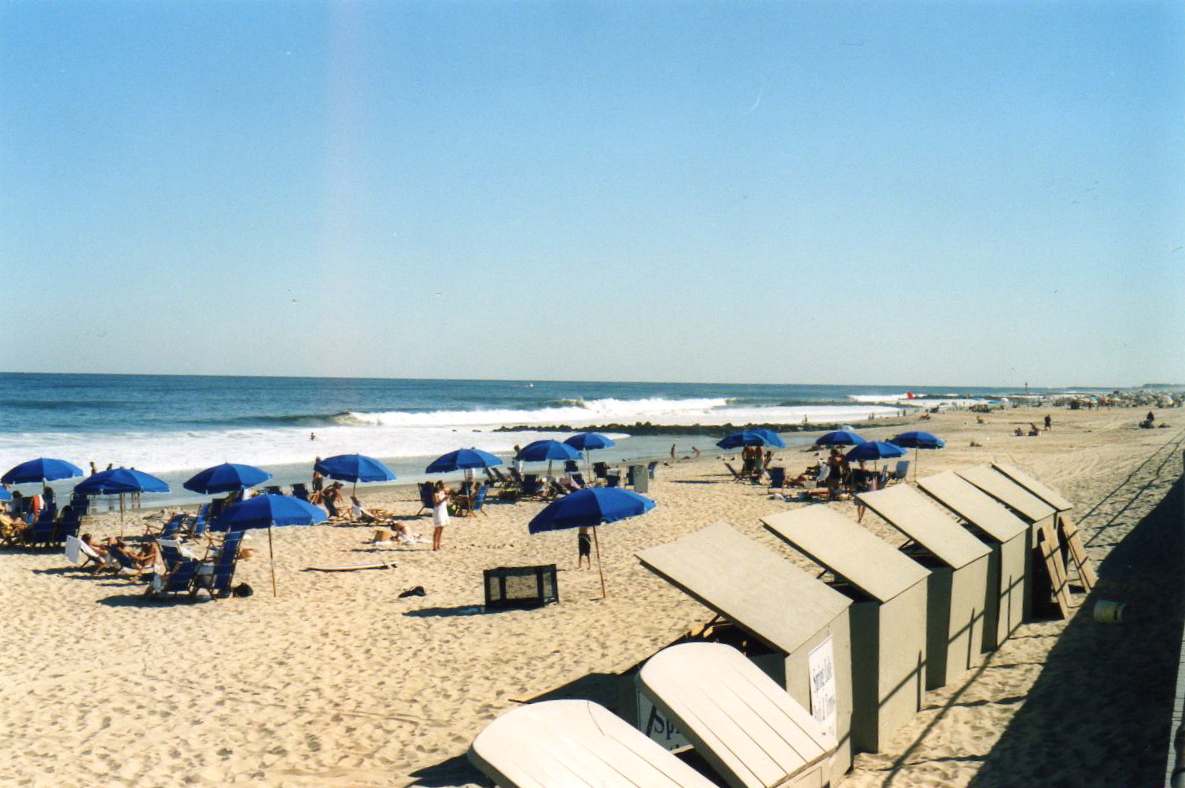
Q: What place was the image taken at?
A: It was taken at the beach.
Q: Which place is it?
A: It is a beach.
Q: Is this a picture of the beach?
A: Yes, it is showing the beach.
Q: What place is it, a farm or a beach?
A: It is a beach.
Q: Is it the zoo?
A: No, it is the beach.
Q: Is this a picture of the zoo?
A: No, the picture is showing the beach.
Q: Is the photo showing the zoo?
A: No, the picture is showing the beach.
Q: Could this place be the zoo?
A: No, it is the beach.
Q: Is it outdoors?
A: Yes, it is outdoors.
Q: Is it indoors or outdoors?
A: It is outdoors.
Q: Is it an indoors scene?
A: No, it is outdoors.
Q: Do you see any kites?
A: No, there are no kites.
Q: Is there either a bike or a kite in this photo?
A: No, there are no kites or bikes.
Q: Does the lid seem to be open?
A: Yes, the lid is open.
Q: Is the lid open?
A: Yes, the lid is open.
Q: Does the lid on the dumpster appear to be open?
A: Yes, the lid is open.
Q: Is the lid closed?
A: No, the lid is open.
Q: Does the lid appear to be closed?
A: No, the lid is open.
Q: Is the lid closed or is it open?
A: The lid is open.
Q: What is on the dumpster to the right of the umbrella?
A: The lid is on the dumpster.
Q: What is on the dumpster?
A: The lid is on the dumpster.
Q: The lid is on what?
A: The lid is on the dumpster.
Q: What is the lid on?
A: The lid is on the dumpster.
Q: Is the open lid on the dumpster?
A: Yes, the lid is on the dumpster.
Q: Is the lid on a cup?
A: No, the lid is on the dumpster.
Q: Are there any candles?
A: No, there are no candles.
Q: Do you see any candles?
A: No, there are no candles.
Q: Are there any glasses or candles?
A: No, there are no candles or glasses.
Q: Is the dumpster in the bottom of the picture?
A: Yes, the dumpster is in the bottom of the image.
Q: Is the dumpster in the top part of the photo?
A: No, the dumpster is in the bottom of the image.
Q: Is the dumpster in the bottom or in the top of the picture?
A: The dumpster is in the bottom of the image.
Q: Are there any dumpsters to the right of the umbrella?
A: Yes, there is a dumpster to the right of the umbrella.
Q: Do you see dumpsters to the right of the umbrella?
A: Yes, there is a dumpster to the right of the umbrella.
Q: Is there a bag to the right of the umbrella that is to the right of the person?
A: No, there is a dumpster to the right of the umbrella.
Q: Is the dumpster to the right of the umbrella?
A: Yes, the dumpster is to the right of the umbrella.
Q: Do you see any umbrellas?
A: Yes, there is an umbrella.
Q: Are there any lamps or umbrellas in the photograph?
A: Yes, there is an umbrella.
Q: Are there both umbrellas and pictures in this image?
A: No, there is an umbrella but no pictures.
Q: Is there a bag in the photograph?
A: No, there are no bags.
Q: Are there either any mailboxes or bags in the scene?
A: No, there are no bags or mailboxes.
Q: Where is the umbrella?
A: The umbrella is on the beach.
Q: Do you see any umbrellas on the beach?
A: Yes, there is an umbrella on the beach.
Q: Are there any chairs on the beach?
A: No, there is an umbrella on the beach.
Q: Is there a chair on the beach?
A: No, there is an umbrella on the beach.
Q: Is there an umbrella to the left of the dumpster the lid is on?
A: Yes, there is an umbrella to the left of the dumpster.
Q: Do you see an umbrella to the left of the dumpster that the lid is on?
A: Yes, there is an umbrella to the left of the dumpster.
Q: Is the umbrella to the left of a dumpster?
A: Yes, the umbrella is to the left of a dumpster.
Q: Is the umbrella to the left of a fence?
A: No, the umbrella is to the left of a dumpster.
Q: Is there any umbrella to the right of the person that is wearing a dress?
A: Yes, there is an umbrella to the right of the person.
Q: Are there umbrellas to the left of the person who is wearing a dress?
A: No, the umbrella is to the right of the person.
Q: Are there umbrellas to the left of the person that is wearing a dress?
A: No, the umbrella is to the right of the person.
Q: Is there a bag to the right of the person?
A: No, there is an umbrella to the right of the person.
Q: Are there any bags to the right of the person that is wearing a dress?
A: No, there is an umbrella to the right of the person.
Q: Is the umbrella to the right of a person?
A: Yes, the umbrella is to the right of a person.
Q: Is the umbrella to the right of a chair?
A: No, the umbrella is to the right of a person.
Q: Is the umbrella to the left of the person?
A: No, the umbrella is to the right of the person.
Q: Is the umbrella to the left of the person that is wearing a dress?
A: No, the umbrella is to the right of the person.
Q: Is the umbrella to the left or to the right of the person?
A: The umbrella is to the right of the person.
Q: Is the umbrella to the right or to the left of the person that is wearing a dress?
A: The umbrella is to the right of the person.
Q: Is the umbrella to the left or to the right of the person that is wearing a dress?
A: The umbrella is to the right of the person.